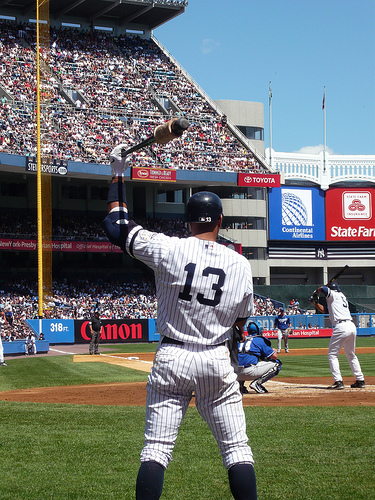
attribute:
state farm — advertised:
[324, 182, 374, 245]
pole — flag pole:
[321, 81, 325, 184]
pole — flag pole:
[265, 80, 273, 165]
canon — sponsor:
[74, 318, 150, 346]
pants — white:
[334, 334, 363, 377]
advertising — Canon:
[77, 304, 141, 350]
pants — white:
[146, 332, 252, 438]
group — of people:
[6, 17, 265, 175]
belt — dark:
[159, 334, 229, 347]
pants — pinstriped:
[132, 339, 265, 498]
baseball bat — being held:
[308, 263, 348, 302]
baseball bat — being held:
[105, 117, 188, 162]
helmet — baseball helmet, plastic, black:
[174, 189, 254, 240]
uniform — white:
[111, 205, 281, 482]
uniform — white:
[111, 211, 327, 355]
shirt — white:
[95, 205, 266, 353]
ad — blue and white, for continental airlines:
[276, 178, 341, 246]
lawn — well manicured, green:
[3, 334, 373, 499]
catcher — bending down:
[236, 319, 282, 393]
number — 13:
[173, 257, 229, 308]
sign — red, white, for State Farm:
[322, 184, 373, 241]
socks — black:
[130, 462, 172, 494]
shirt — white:
[123, 218, 254, 346]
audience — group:
[2, 29, 197, 162]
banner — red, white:
[233, 168, 286, 193]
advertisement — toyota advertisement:
[247, 172, 277, 187]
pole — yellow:
[32, 0, 47, 319]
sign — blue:
[266, 182, 325, 248]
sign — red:
[326, 182, 374, 241]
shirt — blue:
[232, 334, 274, 368]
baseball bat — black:
[118, 119, 188, 155]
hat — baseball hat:
[185, 191, 223, 223]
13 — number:
[177, 260, 226, 308]